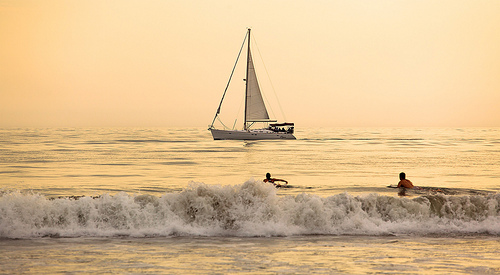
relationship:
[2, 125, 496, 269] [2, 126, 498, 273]
ripples on water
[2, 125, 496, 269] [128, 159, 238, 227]
ripples in water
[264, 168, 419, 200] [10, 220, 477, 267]
people at beach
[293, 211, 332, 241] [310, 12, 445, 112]
badsentence in sky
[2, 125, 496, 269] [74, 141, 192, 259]
ripples in water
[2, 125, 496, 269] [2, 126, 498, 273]
ripples in water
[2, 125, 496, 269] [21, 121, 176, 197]
ripples in water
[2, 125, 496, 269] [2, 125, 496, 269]
ripples in ripples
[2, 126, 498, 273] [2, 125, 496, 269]
water in ripples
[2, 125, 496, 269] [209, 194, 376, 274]
ripples in water